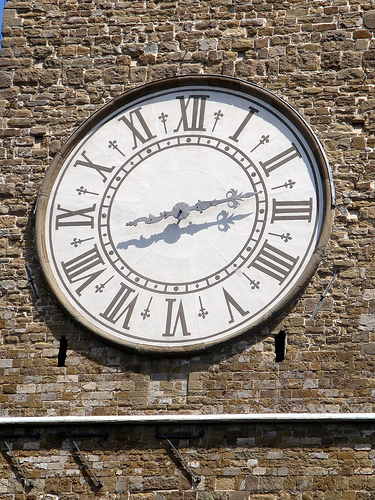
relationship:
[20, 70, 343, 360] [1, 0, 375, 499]
clock on stone wall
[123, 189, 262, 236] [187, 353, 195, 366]
clock has part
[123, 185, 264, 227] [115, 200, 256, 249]
hands casting shadow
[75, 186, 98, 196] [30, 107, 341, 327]
decoration on clock face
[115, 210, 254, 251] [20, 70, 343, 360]
hands on clock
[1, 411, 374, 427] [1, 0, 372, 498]
ledge on stone wall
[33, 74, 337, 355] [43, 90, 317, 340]
clock with roman numerals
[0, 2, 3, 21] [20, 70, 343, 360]
sky behind clock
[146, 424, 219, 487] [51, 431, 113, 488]
metal bracket on metal bracket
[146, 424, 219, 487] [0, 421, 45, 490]
metal bracket on metal bracket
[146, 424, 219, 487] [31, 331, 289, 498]
metal bracket on stone wall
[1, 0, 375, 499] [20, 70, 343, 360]
stone wall under clock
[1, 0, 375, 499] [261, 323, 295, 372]
stone wall under hole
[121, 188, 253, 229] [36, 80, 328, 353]
hand on clock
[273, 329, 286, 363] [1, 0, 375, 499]
spot on stone wall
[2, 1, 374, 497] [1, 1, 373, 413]
brick building on wall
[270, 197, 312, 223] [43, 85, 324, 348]
roman numeral on clock face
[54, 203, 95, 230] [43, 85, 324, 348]
roman numeral on clock face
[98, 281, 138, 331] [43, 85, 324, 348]
roman numeral on clock face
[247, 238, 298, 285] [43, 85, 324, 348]
roman numeral on clock face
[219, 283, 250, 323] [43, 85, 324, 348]
roman numeral on clock face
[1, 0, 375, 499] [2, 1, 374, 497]
stone wall on brick building